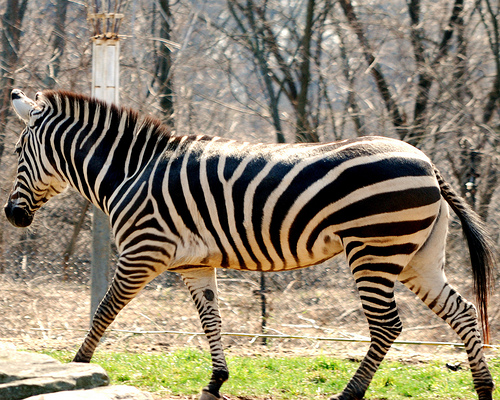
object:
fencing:
[15, 232, 122, 321]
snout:
[2, 202, 20, 223]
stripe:
[128, 151, 185, 260]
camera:
[0, 85, 487, 334]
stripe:
[356, 286, 393, 298]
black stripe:
[349, 262, 408, 273]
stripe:
[351, 241, 419, 258]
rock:
[0, 348, 105, 398]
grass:
[27, 349, 497, 398]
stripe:
[259, 151, 288, 264]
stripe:
[404, 282, 419, 291]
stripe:
[327, 192, 383, 252]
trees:
[336, 3, 480, 138]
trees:
[194, 2, 354, 132]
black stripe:
[332, 213, 440, 238]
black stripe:
[119, 261, 161, 271]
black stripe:
[364, 348, 384, 364]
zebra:
[4, 85, 497, 400]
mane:
[36, 84, 182, 139]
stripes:
[368, 295, 397, 339]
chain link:
[22, 223, 99, 317]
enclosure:
[12, 51, 495, 361]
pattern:
[139, 160, 411, 251]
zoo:
[9, 47, 499, 387]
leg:
[399, 190, 494, 398]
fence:
[6, 176, 490, 291]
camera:
[375, 50, 483, 382]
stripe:
[112, 109, 123, 208]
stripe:
[113, 102, 129, 212]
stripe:
[105, 98, 126, 232]